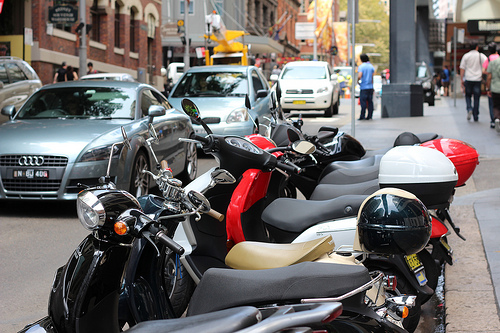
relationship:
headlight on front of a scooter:
[74, 192, 101, 236] [48, 176, 420, 332]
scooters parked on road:
[68, 120, 481, 333] [1, 74, 330, 323]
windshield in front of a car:
[24, 89, 137, 118] [1, 78, 196, 208]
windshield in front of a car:
[178, 72, 248, 97] [164, 63, 278, 154]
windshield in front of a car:
[285, 65, 324, 82] [271, 59, 345, 120]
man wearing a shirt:
[351, 51, 383, 125] [357, 62, 376, 93]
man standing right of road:
[351, 51, 383, 125] [1, 74, 330, 323]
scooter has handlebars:
[48, 176, 420, 332] [76, 178, 180, 271]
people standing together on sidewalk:
[436, 27, 500, 126] [353, 90, 500, 333]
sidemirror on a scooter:
[120, 127, 134, 152] [48, 176, 420, 332]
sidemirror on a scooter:
[188, 189, 216, 220] [48, 176, 420, 332]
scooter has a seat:
[48, 176, 420, 332] [223, 236, 336, 269]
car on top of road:
[271, 59, 345, 120] [1, 74, 330, 323]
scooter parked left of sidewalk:
[48, 176, 420, 332] [353, 90, 500, 333]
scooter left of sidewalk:
[48, 176, 420, 332] [353, 90, 500, 333]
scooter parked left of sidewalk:
[268, 112, 481, 186] [353, 90, 500, 333]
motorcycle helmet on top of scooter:
[350, 188, 437, 261] [48, 176, 420, 332]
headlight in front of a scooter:
[74, 192, 101, 236] [48, 176, 420, 332]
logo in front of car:
[19, 155, 47, 167] [1, 78, 196, 208]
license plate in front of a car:
[11, 168, 51, 183] [1, 78, 196, 208]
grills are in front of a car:
[6, 180, 59, 193] [1, 78, 196, 208]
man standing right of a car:
[351, 51, 383, 125] [271, 59, 345, 120]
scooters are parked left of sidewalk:
[68, 120, 481, 333] [353, 90, 500, 333]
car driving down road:
[1, 78, 196, 208] [1, 74, 330, 323]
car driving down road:
[164, 63, 278, 154] [1, 74, 330, 323]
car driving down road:
[271, 59, 345, 120] [1, 74, 330, 323]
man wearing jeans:
[351, 51, 383, 125] [359, 90, 377, 123]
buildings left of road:
[19, 1, 344, 84] [1, 74, 330, 323]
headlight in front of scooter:
[74, 192, 101, 236] [48, 176, 420, 332]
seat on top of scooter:
[223, 236, 336, 269] [48, 176, 420, 332]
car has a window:
[1, 78, 196, 208] [138, 91, 163, 117]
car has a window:
[164, 63, 278, 154] [249, 70, 266, 101]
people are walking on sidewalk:
[436, 27, 500, 126] [353, 90, 500, 333]